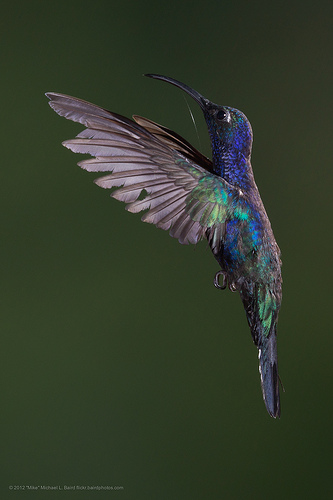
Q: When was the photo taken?
A: 2012.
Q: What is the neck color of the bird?
A: Blue.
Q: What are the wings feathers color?
A: Grey.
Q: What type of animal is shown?
A: Bird.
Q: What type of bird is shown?
A: Hummingbird.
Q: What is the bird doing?
A: Flying.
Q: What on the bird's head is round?
A: Eyes.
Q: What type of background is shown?
A: Solid color.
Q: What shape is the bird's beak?
A: Curved.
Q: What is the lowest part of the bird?
A: Tail feathers.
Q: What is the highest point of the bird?
A: Beak.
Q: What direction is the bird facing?
A: Left.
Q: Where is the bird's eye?
A: On the head.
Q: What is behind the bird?
A: A green background.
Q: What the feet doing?
A: They are curled up.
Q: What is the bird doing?
A: Flying.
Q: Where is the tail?
A: At the bottom of the bird.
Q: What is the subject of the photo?
A: Animal.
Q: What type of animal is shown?
A: Bird.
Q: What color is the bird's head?
A: Blue.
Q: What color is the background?
A: Green.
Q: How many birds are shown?
A: ONe.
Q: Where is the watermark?
A: Bottom left corner.